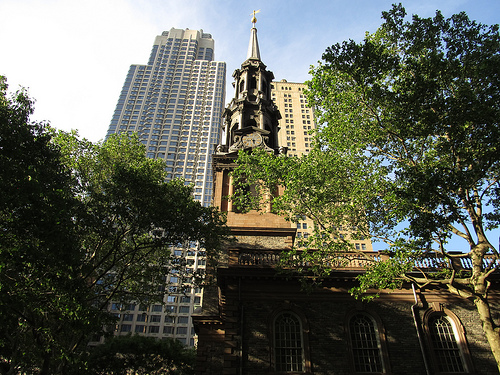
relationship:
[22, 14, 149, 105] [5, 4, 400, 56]
clouds in sky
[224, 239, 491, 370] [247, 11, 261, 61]
church has top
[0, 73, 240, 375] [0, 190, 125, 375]
tree next to church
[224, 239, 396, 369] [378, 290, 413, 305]
church has exterior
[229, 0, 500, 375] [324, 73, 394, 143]
tree has leaves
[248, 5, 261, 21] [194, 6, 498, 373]
cross atop building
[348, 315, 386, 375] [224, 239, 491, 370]
window on church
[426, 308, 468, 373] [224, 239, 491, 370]
window on church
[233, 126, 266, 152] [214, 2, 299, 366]
clock in tower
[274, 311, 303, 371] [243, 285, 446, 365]
window in stone building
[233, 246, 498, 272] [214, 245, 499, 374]
stone fence on building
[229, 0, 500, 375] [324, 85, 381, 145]
tree has leaves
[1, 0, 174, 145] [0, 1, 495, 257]
cloud in sky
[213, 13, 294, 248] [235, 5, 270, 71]
tower has steeple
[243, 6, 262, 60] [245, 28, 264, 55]
weather vane on top of steeple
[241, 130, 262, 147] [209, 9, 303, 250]
clock in front of tower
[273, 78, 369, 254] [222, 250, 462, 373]
building on back of building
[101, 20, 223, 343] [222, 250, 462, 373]
building on back of building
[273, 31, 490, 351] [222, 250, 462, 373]
tree on front building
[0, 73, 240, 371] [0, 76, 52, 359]
tree with green leaves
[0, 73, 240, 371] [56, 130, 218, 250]
tree with green leaves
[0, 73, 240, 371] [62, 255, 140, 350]
tree with green leaves